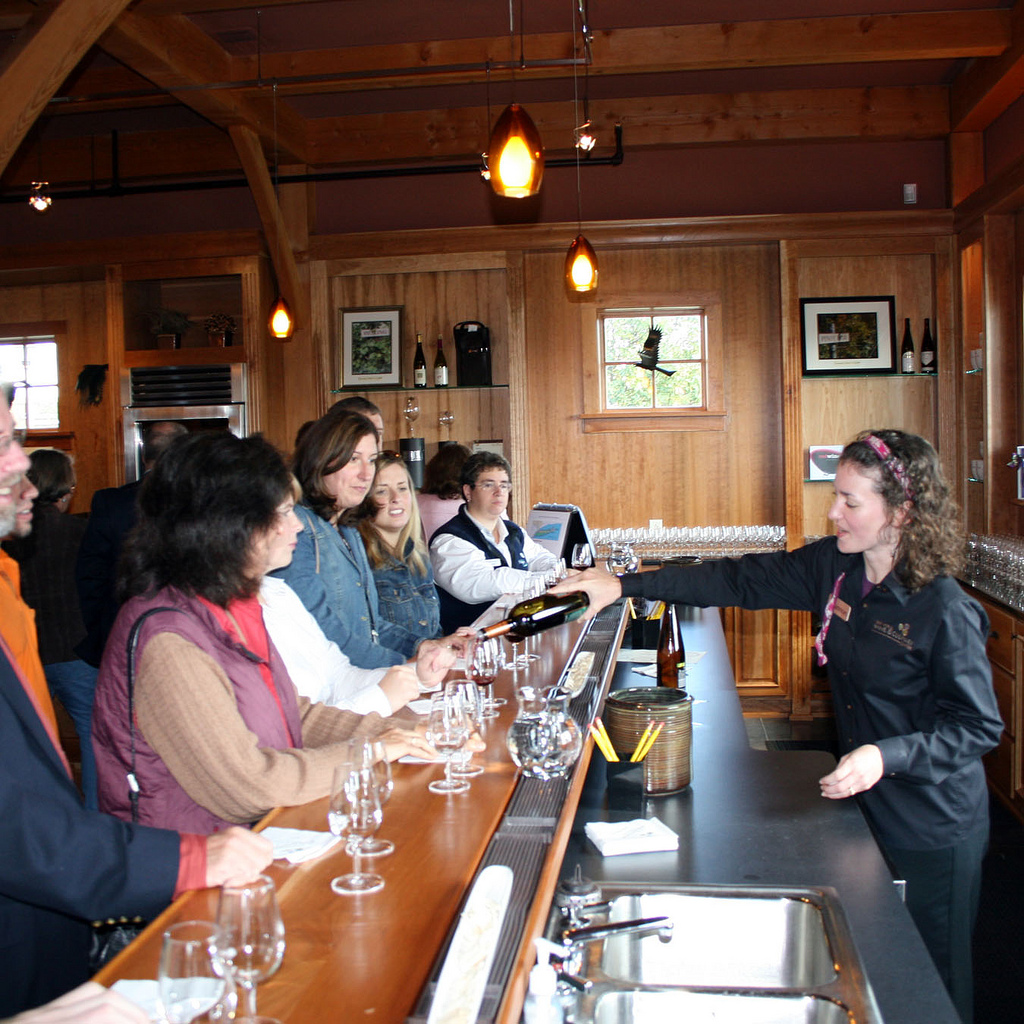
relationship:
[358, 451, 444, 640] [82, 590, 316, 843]
person in vest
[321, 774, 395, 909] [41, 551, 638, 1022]
glasses on bar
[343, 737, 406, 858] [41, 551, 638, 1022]
glasses on bar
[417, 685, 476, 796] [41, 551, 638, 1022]
glasses on bar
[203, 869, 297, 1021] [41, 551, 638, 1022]
glasses on bar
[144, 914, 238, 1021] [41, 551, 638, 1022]
glasses on bar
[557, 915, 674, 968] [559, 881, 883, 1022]
faucet on basin sink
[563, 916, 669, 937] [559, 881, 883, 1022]
faucet on basin sink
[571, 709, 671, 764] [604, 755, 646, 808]
pencils in cup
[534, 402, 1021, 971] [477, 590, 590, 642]
bartender pours bottle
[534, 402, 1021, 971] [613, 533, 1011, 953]
bartender dress black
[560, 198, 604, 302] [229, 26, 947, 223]
light hangs on ceiling